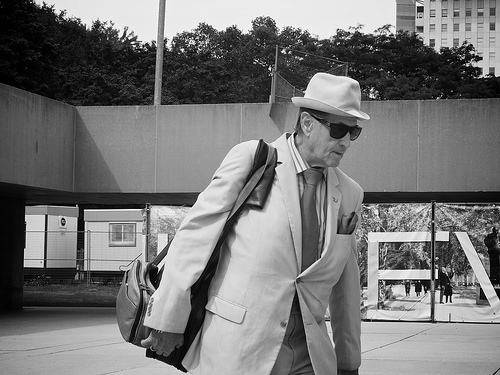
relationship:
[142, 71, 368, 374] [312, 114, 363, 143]
man wearing sunglasses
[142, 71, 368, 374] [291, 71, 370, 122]
man wearing hat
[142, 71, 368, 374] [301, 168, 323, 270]
man wearing tie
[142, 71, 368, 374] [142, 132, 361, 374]
man wearing suit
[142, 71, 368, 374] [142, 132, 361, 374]
man wearing jacket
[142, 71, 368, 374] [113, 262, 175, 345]
man holding bag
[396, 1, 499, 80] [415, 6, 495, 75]
building with windows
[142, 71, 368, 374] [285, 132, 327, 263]
man wearing shirt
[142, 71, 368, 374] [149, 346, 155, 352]
man wearing ring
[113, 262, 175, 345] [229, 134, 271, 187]
bag over shoulder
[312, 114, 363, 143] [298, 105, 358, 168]
sunglasses on face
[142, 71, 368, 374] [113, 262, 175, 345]
man with bag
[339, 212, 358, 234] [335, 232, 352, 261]
tissue in pocket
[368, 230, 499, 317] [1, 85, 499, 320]
letters on wall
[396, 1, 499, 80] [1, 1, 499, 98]
building in background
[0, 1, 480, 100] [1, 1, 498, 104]
tops of trees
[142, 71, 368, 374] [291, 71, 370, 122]
man wears hat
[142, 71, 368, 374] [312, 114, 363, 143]
man wears glasses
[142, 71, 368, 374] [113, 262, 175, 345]
man carries bag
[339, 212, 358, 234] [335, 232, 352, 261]
kerchief in pocket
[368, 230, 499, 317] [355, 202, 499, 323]
letters outside window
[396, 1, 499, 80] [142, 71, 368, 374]
building behind man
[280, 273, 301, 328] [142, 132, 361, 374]
buttons on jacket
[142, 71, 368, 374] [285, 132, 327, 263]
man wears shirt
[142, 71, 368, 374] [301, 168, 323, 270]
man wears necktie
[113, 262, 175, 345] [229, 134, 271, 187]
bag on shoulder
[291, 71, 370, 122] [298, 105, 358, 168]
fedora on head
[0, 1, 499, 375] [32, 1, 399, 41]
photo during day